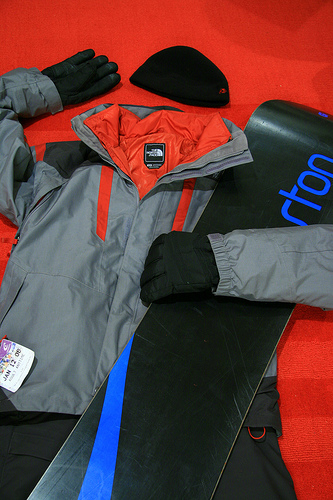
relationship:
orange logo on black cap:
[216, 88, 227, 92] [128, 43, 228, 110]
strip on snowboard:
[74, 327, 141, 498] [22, 64, 326, 498]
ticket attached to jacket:
[0, 334, 36, 395] [0, 56, 322, 431]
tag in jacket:
[143, 142, 164, 169] [0, 56, 322, 431]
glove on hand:
[137, 231, 219, 307] [138, 227, 218, 307]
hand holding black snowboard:
[137, 227, 226, 309] [24, 99, 332, 499]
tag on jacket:
[249, 416, 276, 443] [0, 56, 322, 431]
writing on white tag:
[4, 347, 25, 378] [0, 333, 37, 396]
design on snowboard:
[85, 358, 131, 474] [73, 98, 330, 498]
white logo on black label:
[145, 148, 162, 156] [143, 142, 164, 168]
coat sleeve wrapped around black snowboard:
[153, 228, 332, 296] [24, 99, 332, 499]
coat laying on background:
[1, 63, 331, 436] [0, 0, 333, 498]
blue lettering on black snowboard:
[279, 153, 332, 225] [24, 93, 332, 498]